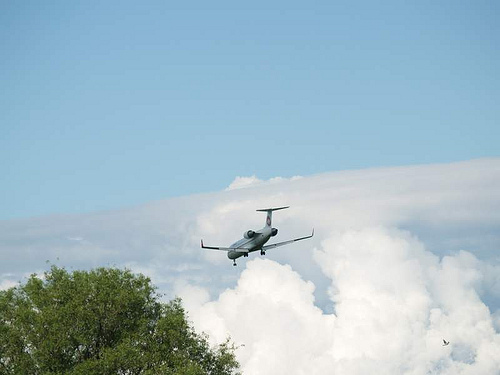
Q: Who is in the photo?
A: No one.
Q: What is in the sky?
A: A plane.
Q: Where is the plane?
A: Above a tree.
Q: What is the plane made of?
A: Metal.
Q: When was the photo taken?
A: During the day.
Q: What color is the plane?
A: Silver.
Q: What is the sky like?
A: Clear.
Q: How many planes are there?
A: One.